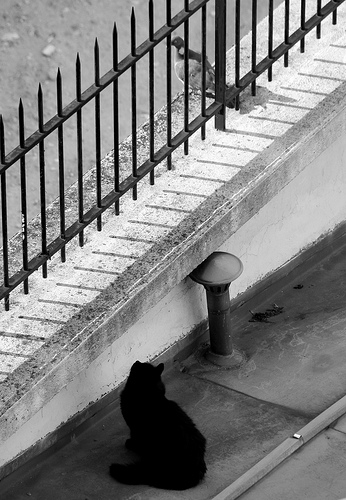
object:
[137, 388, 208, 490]
back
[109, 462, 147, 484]
tail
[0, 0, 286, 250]
ledge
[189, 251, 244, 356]
pipe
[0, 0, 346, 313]
fence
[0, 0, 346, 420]
ground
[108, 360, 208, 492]
cat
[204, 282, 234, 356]
tile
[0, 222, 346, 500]
concrete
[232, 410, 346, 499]
road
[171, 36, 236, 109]
bird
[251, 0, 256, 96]
bars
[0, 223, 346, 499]
floor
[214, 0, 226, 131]
bar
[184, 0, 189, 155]
bar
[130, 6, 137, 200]
bar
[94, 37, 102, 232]
bar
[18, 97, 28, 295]
bar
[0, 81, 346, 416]
ledge